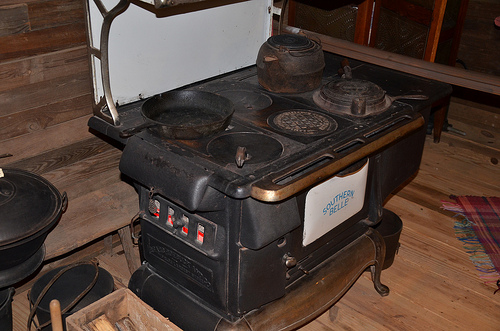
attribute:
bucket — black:
[366, 208, 402, 269]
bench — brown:
[1, 169, 140, 313]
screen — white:
[90, 1, 270, 104]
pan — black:
[1, 169, 69, 291]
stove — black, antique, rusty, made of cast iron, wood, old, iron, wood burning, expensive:
[88, 59, 427, 330]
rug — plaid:
[437, 195, 498, 294]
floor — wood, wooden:
[7, 89, 496, 327]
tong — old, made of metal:
[26, 259, 100, 327]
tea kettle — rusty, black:
[257, 34, 327, 95]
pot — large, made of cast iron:
[27, 265, 115, 330]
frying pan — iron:
[120, 88, 235, 137]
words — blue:
[321, 188, 356, 217]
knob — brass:
[283, 254, 297, 268]